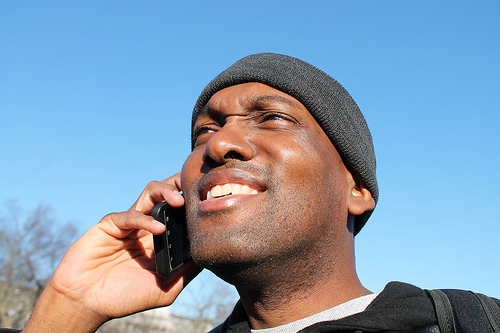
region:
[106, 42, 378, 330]
man holding his phone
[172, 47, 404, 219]
man is wearing a hat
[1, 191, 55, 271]
Branche on the background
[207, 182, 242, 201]
the two front teeth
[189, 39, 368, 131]
A black bonnet on the mans' head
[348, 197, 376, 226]
Tip of the left ear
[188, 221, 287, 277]
Small hairs on the jaw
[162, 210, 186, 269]
A phone four main buttons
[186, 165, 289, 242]
A smilling lips of a man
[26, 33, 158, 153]
Clear blue sky in the background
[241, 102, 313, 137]
There are wrinkles around the eye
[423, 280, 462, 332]
A black thin strap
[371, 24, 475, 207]
The sky is clear and blue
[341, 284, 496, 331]
The man is wearing a black sweater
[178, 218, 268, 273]
The chin of the man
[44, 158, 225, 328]
The man is holding his phone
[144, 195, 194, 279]
The cell phone is the color black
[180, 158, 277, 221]
The man is smiling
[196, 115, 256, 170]
The nose of the man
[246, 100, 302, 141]
The eye of the man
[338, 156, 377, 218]
The ear of the man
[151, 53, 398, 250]
The man has on a beanie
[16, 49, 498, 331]
THIS IS A MAN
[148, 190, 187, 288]
HE HAS A CELL PHONE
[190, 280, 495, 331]
HE HAS ON A BLACK JACKET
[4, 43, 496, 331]
THE MAN IS SMILING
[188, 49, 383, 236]
HE HAS A GRAY HAT ON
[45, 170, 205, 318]
THIS IS HIS HAND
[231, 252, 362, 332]
THATS THE MAN'S NECK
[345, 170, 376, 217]
THIS IS HIS EAR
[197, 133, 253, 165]
THIS IS HIS NOSE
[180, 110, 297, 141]
THESE ARE HIS EYES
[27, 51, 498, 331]
Black man holding mobile phone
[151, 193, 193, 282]
Mobile phone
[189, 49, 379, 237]
Charcoal gray stocking cap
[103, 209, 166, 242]
Pinky finger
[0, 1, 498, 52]
Cloudless blue sky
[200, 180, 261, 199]
White teeth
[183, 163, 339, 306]
Dark stubble on chin and neck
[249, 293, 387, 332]
White tee shirt neck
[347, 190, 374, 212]
Ear lobe of ear partially covered by stocking cap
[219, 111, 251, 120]
Horizontal crease between eyes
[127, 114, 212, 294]
a man holding a cell phone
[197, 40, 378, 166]
a man wearing a hat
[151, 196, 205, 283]
a black cell phone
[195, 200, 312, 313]
a man with facial hair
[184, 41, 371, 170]
a man wearing a grey hat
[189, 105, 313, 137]
a man with brown eyes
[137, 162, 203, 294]
a man holding a black cell phone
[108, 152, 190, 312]
a touching his face using a cell phone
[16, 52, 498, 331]
man talking on phone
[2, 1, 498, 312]
sky is light blue and cloudless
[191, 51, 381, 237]
black knitted cap on head